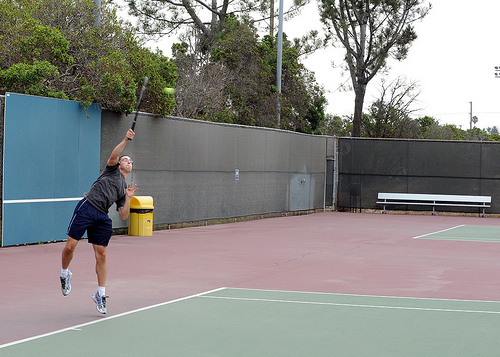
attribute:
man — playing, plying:
[93, 133, 149, 207]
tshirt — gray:
[83, 166, 134, 212]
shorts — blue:
[65, 203, 118, 248]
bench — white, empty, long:
[371, 188, 493, 217]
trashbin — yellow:
[126, 190, 158, 241]